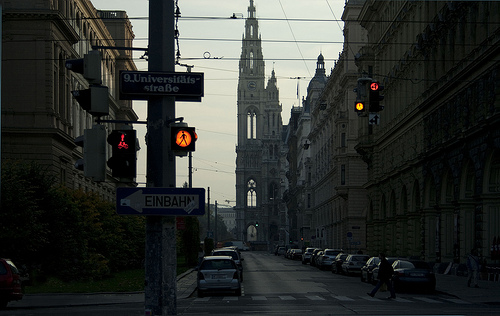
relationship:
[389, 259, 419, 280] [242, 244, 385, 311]
car parked along road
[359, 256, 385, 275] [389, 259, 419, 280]
car parked along car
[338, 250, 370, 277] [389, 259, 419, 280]
car parked along car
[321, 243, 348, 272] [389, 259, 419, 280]
car parked along car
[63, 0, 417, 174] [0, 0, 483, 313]
wires in street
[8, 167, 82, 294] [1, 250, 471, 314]
trees along street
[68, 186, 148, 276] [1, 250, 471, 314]
bushes along street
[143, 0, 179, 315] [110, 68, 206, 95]
pole holding sign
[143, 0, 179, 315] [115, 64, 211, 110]
pole holding sign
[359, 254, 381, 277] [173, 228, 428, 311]
car parked on street street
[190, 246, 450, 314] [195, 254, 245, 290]
street with car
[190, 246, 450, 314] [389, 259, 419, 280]
street with car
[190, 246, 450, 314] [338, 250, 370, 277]
street with car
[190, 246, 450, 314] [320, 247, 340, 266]
street with vehicle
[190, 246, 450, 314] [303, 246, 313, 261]
street with vehicle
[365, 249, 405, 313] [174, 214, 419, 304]
pedestrian crossing street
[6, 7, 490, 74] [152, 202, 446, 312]
cables running across street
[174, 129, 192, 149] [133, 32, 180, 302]
crosswalk light on pole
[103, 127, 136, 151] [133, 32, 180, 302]
light on pole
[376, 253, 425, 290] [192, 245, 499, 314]
car parked on street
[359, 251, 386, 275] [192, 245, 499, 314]
car parked on street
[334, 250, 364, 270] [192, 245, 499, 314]
car parked on street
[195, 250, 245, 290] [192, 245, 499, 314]
car parked on street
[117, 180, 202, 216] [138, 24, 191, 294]
signs on pole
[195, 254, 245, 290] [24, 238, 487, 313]
car parked on street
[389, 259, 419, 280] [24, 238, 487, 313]
car parked on street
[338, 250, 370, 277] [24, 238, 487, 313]
car parked on street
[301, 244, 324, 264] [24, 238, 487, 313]
cars parked on street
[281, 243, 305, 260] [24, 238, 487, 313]
cars parked on street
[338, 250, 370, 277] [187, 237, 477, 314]
car on street